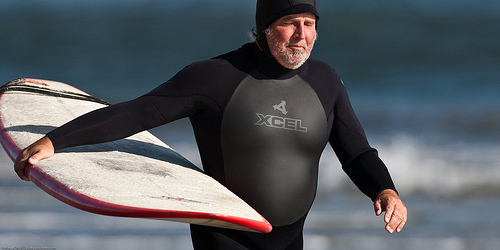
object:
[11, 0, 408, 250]
man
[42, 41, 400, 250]
suit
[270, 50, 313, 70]
beard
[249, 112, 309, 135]
xcel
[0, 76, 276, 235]
surfboard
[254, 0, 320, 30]
cap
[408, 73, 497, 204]
sea